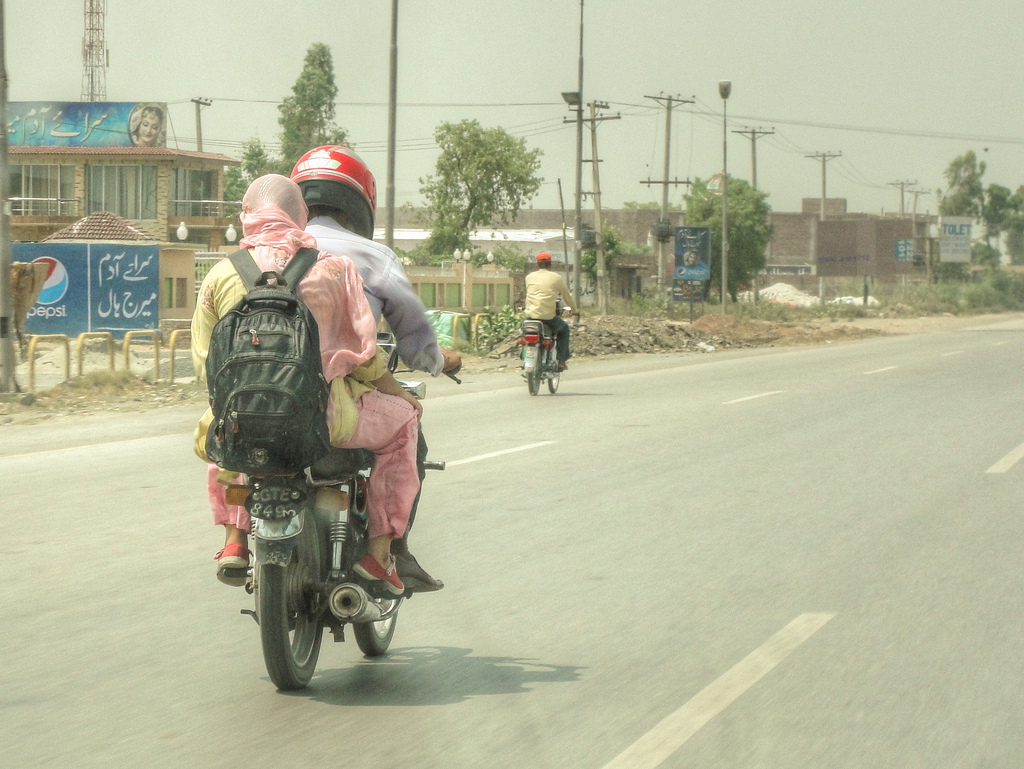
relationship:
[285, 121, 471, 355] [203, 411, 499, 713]
person riding on motorcycle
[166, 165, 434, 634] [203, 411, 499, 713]
person riding on motorcycle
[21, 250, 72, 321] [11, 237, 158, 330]
logo on sign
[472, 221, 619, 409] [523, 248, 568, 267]
man wearing red hat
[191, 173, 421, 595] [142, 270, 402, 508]
person has a backpack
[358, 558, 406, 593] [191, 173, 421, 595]
shoe on person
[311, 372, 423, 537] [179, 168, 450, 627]
pants on woman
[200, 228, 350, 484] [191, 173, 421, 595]
backpack on person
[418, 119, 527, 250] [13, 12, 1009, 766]
tree in city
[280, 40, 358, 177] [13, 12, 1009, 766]
tree in city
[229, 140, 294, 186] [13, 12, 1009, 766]
tree in city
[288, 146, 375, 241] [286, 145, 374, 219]
head on head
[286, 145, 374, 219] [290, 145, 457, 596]
head of person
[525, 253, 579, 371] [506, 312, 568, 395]
man on motorcycle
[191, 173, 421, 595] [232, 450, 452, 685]
person on motorcycle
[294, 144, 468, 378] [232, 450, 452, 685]
man on motorcycle